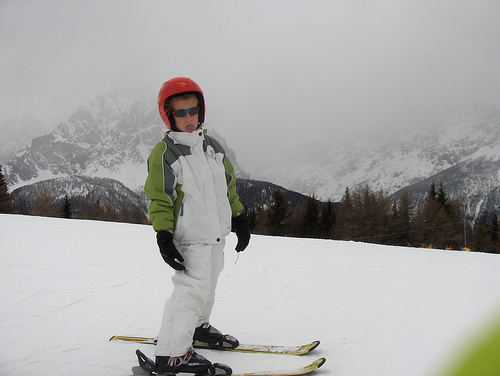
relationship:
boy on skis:
[143, 70, 235, 373] [103, 329, 330, 375]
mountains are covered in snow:
[12, 61, 147, 218] [361, 304, 411, 337]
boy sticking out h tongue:
[143, 70, 235, 373] [186, 124, 196, 136]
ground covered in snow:
[0, 214, 492, 355] [361, 304, 411, 337]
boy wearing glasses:
[143, 70, 235, 373] [170, 105, 203, 118]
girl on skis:
[144, 72, 236, 375] [103, 329, 330, 375]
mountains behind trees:
[12, 61, 147, 218] [34, 194, 115, 214]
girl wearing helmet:
[144, 72, 236, 375] [158, 78, 207, 131]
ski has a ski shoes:
[97, 355, 328, 372] [153, 350, 214, 374]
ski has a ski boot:
[107, 333, 324, 358] [194, 323, 230, 352]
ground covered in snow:
[0, 189, 492, 342] [361, 304, 411, 337]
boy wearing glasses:
[143, 70, 235, 373] [170, 108, 201, 118]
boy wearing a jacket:
[143, 70, 235, 373] [151, 130, 245, 228]